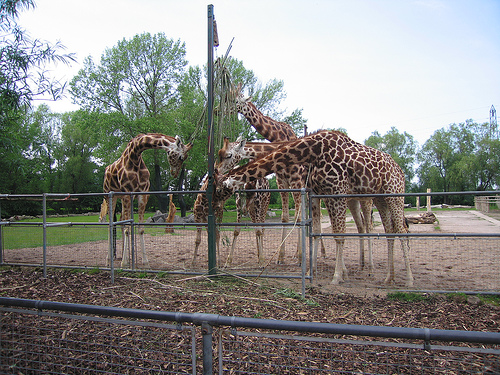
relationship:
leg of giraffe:
[191, 212, 203, 269] [192, 133, 244, 261]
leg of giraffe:
[393, 201, 418, 284] [207, 127, 414, 295]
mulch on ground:
[161, 290, 386, 355] [1, 265, 497, 373]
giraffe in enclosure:
[93, 130, 195, 269] [2, 181, 498, 371]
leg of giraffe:
[320, 190, 352, 285] [207, 127, 414, 295]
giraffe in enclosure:
[211, 72, 309, 271] [2, 181, 498, 371]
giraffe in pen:
[207, 127, 414, 295] [4, 177, 498, 298]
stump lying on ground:
[406, 209, 438, 225] [5, 202, 496, 373]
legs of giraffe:
[251, 201, 413, 286] [93, 64, 412, 281]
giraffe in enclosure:
[93, 64, 412, 281] [2, 181, 498, 371]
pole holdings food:
[217, 0, 224, 272] [211, 81, 226, 122]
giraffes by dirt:
[159, 101, 384, 211] [2, 200, 496, 296]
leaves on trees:
[66, 30, 203, 105] [1, 29, 497, 199]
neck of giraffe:
[245, 102, 277, 133] [217, 86, 326, 263]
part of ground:
[358, 311, 369, 325] [4, 275, 488, 365]